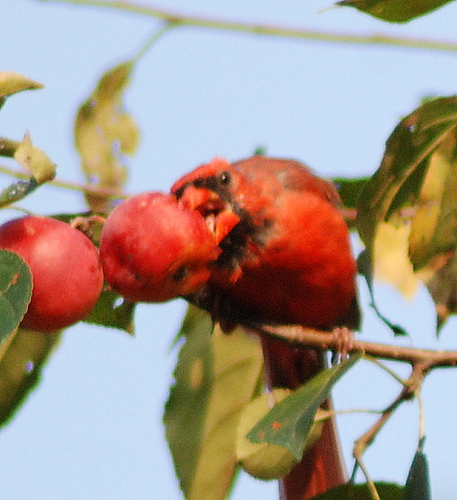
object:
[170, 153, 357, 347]
bird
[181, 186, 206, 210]
beak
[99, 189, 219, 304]
fruit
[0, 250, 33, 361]
leaf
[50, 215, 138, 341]
leaf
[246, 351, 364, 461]
leaf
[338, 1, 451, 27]
leaf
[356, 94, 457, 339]
leaf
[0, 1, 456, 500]
sky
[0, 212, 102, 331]
fruit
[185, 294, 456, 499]
branch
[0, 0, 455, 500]
tree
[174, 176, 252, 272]
marking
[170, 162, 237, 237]
face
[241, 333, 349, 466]
tail feathers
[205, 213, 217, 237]
tongue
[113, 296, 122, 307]
hole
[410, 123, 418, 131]
hole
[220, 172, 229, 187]
eye